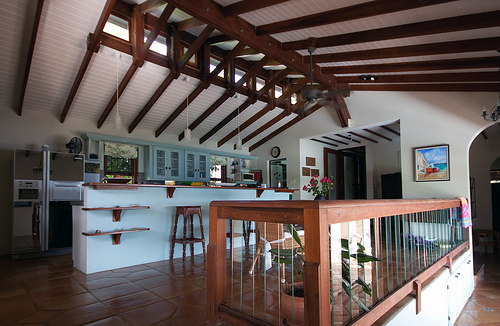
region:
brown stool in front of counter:
[139, 173, 226, 274]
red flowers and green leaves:
[284, 165, 341, 224]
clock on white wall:
[259, 134, 295, 174]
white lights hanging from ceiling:
[103, 54, 282, 160]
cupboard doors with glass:
[147, 139, 227, 184]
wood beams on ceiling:
[84, 7, 450, 137]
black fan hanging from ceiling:
[279, 25, 370, 121]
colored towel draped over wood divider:
[433, 183, 498, 245]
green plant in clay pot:
[252, 216, 416, 322]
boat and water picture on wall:
[398, 130, 464, 185]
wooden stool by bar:
[168, 204, 206, 262]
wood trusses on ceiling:
[19, 17, 496, 132]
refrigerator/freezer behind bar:
[10, 151, 89, 261]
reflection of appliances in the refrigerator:
[11, 177, 82, 204]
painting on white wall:
[411, 145, 451, 182]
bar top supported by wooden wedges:
[86, 183, 293, 197]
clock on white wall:
[268, 146, 282, 158]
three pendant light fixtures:
[106, 52, 245, 149]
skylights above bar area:
[98, 1, 310, 122]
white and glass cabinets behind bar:
[83, 142, 259, 182]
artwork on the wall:
[412, 139, 455, 181]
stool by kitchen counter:
[166, 205, 204, 278]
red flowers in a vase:
[307, 177, 333, 214]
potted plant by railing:
[271, 233, 353, 324]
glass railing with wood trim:
[323, 205, 460, 306]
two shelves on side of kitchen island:
[81, 200, 158, 254]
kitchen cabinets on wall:
[151, 146, 211, 186]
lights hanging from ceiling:
[102, 103, 264, 151]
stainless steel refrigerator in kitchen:
[10, 145, 85, 267]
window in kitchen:
[102, 140, 144, 185]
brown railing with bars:
[200, 188, 467, 325]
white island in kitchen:
[78, 180, 299, 262]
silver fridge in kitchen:
[13, 147, 80, 246]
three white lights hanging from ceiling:
[103, 60, 255, 155]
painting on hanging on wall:
[407, 147, 449, 182]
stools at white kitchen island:
[164, 199, 259, 256]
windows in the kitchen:
[88, 137, 232, 182]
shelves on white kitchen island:
[80, 196, 144, 240]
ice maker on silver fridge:
[13, 177, 40, 204]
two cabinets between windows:
[152, 145, 205, 180]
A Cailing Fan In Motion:
[281, 26, 361, 130]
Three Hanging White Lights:
[107, 95, 257, 152]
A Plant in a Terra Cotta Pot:
[263, 229, 358, 321]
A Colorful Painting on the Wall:
[400, 131, 455, 192]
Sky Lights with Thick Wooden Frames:
[208, 61, 305, 113]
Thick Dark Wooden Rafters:
[220, 1, 495, 97]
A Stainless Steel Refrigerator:
[4, 138, 95, 295]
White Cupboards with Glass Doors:
[143, 139, 216, 186]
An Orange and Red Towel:
[439, 186, 477, 250]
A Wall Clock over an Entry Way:
[263, 143, 305, 191]